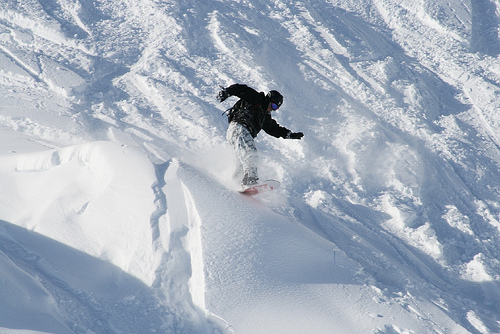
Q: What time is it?
A: Afternoon.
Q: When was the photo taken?
A: During the daytime.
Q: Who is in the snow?
A: A man.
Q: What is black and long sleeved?
A: The jacket.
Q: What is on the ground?
A: Snow.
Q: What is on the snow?
A: Shadow.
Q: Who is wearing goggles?
A: The man.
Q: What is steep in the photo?
A: Mountain.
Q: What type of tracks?
A: Snowboard.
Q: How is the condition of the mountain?
A: Covered with snow.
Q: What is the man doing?
A: Riding off a jump.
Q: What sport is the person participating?
A: Snowboarding.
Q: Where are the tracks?
A: In the snow.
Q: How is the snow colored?
A: White.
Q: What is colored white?
A: Snow.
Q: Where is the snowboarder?
A: On a steep slope.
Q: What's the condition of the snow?
A: Powdered and plentiful.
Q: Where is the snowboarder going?
A: Over the snow mound.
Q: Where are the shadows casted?
A: Around the snow.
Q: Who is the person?
A: Snowboarder.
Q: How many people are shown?
A: One.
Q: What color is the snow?
A: White.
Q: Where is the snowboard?
A: In snow.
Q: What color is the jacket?
A: Black.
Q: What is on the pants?
A: The snow.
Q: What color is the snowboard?
A: Red.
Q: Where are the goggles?
A: Man's face.